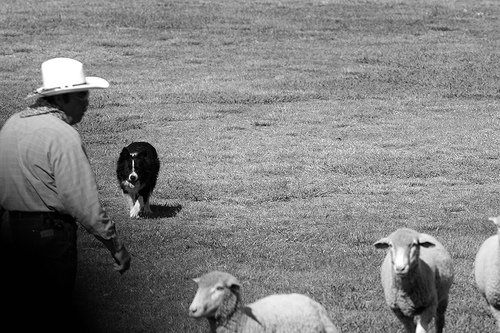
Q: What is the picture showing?
A: It is showing a field.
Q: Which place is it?
A: It is a field.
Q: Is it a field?
A: Yes, it is a field.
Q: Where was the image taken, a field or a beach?
A: It was taken at a field.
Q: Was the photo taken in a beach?
A: No, the picture was taken in a field.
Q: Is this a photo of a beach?
A: No, the picture is showing a field.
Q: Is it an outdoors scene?
A: Yes, it is outdoors.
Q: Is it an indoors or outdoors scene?
A: It is outdoors.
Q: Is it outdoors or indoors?
A: It is outdoors.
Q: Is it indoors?
A: No, it is outdoors.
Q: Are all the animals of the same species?
A: No, there are both sheep and dogs.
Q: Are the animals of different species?
A: Yes, they are sheep and dogs.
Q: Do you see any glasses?
A: No, there are no glasses.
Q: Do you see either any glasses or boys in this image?
A: No, there are no glasses or boys.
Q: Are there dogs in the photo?
A: Yes, there is a dog.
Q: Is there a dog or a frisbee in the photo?
A: Yes, there is a dog.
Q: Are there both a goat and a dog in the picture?
A: No, there is a dog but no goats.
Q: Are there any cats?
A: No, there are no cats.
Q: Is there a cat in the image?
A: No, there are no cats.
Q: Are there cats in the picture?
A: No, there are no cats.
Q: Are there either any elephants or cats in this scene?
A: No, there are no cats or elephants.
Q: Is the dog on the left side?
A: Yes, the dog is on the left of the image.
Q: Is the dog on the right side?
A: No, the dog is on the left of the image.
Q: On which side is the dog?
A: The dog is on the left of the image.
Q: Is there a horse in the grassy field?
A: No, there is a dog in the field.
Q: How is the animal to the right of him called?
A: The animal is a dog.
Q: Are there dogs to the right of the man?
A: Yes, there is a dog to the right of the man.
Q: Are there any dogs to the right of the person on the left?
A: Yes, there is a dog to the right of the man.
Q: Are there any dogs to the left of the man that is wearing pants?
A: No, the dog is to the right of the man.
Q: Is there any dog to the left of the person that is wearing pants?
A: No, the dog is to the right of the man.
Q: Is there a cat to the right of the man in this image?
A: No, there is a dog to the right of the man.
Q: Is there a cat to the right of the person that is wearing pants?
A: No, there is a dog to the right of the man.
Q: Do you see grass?
A: Yes, there is grass.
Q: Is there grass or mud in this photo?
A: Yes, there is grass.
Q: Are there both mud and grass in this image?
A: No, there is grass but no mud.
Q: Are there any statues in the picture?
A: No, there are no statues.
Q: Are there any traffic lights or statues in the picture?
A: No, there are no statues or traffic lights.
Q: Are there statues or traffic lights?
A: No, there are no statues or traffic lights.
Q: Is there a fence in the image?
A: No, there are no fences.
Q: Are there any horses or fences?
A: No, there are no fences or horses.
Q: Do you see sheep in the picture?
A: Yes, there is a sheep.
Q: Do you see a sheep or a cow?
A: Yes, there is a sheep.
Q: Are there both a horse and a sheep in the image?
A: No, there is a sheep but no horses.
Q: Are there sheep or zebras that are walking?
A: Yes, the sheep is walking.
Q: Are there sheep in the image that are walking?
A: Yes, there is a sheep that is walking.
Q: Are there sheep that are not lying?
A: Yes, there is a sheep that is walking.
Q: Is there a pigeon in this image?
A: No, there are no pigeons.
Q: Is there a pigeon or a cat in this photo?
A: No, there are no pigeons or cats.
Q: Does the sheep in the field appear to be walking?
A: Yes, the sheep is walking.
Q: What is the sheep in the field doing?
A: The sheep is walking.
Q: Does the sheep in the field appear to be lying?
A: No, the sheep is walking.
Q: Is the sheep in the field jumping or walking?
A: The sheep is walking.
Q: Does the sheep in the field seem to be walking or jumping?
A: The sheep is walking.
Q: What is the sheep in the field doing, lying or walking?
A: The sheep is walking.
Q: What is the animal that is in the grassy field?
A: The animal is a sheep.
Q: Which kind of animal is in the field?
A: The animal is a sheep.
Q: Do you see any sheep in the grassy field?
A: Yes, there is a sheep in the field.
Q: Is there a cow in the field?
A: No, there is a sheep in the field.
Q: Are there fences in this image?
A: No, there are no fences.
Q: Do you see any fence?
A: No, there are no fences.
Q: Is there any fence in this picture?
A: No, there are no fences.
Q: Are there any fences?
A: No, there are no fences.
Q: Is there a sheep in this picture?
A: Yes, there is a sheep.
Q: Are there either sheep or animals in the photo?
A: Yes, there is a sheep.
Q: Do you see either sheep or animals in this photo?
A: Yes, there is a sheep.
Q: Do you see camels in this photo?
A: No, there are no camels.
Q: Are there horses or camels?
A: No, there are no camels or horses.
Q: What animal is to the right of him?
A: The animal is a sheep.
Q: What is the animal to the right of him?
A: The animal is a sheep.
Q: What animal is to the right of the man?
A: The animal is a sheep.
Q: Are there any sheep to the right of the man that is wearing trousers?
A: Yes, there is a sheep to the right of the man.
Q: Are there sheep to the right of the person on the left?
A: Yes, there is a sheep to the right of the man.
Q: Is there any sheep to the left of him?
A: No, the sheep is to the right of the man.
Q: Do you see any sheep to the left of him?
A: No, the sheep is to the right of the man.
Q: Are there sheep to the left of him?
A: No, the sheep is to the right of the man.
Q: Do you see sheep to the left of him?
A: No, the sheep is to the right of the man.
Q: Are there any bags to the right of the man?
A: No, there is a sheep to the right of the man.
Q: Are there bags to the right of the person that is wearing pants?
A: No, there is a sheep to the right of the man.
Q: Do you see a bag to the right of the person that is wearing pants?
A: No, there is a sheep to the right of the man.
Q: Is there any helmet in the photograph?
A: No, there are no helmets.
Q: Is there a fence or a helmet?
A: No, there are no helmets or fences.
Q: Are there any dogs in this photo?
A: Yes, there is a dog.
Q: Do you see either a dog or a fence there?
A: Yes, there is a dog.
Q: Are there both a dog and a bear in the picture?
A: No, there is a dog but no bears.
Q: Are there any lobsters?
A: No, there are no lobsters.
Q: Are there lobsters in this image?
A: No, there are no lobsters.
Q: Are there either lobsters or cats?
A: No, there are no lobsters or cats.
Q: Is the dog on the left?
A: Yes, the dog is on the left of the image.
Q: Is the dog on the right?
A: No, the dog is on the left of the image.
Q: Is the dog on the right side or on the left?
A: The dog is on the left of the image.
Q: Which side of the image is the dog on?
A: The dog is on the left of the image.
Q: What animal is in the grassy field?
A: The animal is a dog.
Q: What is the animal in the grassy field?
A: The animal is a dog.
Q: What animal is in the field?
A: The animal is a dog.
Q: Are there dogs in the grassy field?
A: Yes, there is a dog in the field.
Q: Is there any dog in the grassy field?
A: Yes, there is a dog in the field.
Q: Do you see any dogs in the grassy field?
A: Yes, there is a dog in the field.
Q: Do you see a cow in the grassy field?
A: No, there is a dog in the field.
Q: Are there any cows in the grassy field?
A: No, there is a dog in the field.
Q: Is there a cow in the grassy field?
A: No, there is a dog in the field.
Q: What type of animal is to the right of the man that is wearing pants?
A: The animal is a dog.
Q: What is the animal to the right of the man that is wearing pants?
A: The animal is a dog.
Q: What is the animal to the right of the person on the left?
A: The animal is a dog.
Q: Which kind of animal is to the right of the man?
A: The animal is a dog.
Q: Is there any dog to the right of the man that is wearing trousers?
A: Yes, there is a dog to the right of the man.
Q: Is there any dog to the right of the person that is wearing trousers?
A: Yes, there is a dog to the right of the man.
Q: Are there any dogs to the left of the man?
A: No, the dog is to the right of the man.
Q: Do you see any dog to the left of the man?
A: No, the dog is to the right of the man.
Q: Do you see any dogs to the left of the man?
A: No, the dog is to the right of the man.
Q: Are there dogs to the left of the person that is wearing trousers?
A: No, the dog is to the right of the man.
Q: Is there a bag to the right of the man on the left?
A: No, there is a dog to the right of the man.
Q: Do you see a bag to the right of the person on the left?
A: No, there is a dog to the right of the man.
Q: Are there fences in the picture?
A: No, there are no fences.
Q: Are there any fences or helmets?
A: No, there are no fences or helmets.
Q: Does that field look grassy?
A: Yes, the field is grassy.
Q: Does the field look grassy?
A: Yes, the field is grassy.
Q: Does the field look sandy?
A: No, the field is grassy.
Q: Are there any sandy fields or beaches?
A: No, there is a field but it is grassy.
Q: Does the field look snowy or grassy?
A: The field is grassy.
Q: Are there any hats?
A: Yes, there is a hat.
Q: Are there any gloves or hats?
A: Yes, there is a hat.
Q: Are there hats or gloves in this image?
A: Yes, there is a hat.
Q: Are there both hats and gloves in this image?
A: Yes, there are both a hat and gloves.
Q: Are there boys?
A: No, there are no boys.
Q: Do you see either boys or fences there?
A: No, there are no boys or fences.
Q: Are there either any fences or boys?
A: No, there are no boys or fences.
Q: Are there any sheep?
A: Yes, there is a sheep.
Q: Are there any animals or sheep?
A: Yes, there is a sheep.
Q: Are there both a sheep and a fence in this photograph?
A: No, there is a sheep but no fences.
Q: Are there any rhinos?
A: No, there are no rhinos.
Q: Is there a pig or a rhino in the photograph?
A: No, there are no rhinos or pigs.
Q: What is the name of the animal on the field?
A: The animal is a sheep.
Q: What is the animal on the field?
A: The animal is a sheep.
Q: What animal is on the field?
A: The animal is a sheep.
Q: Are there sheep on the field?
A: Yes, there is a sheep on the field.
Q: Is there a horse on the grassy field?
A: No, there is a sheep on the field.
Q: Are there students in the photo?
A: No, there are no students.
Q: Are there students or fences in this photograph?
A: No, there are no students or fences.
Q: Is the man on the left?
A: Yes, the man is on the left of the image.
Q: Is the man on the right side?
A: No, the man is on the left of the image.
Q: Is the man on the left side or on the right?
A: The man is on the left of the image.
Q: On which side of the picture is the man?
A: The man is on the left of the image.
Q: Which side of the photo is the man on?
A: The man is on the left of the image.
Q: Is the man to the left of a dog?
A: Yes, the man is to the left of a dog.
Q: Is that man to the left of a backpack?
A: No, the man is to the left of a dog.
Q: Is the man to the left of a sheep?
A: Yes, the man is to the left of a sheep.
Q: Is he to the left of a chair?
A: No, the man is to the left of a sheep.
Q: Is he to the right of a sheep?
A: No, the man is to the left of a sheep.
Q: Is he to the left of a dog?
A: Yes, the man is to the left of a dog.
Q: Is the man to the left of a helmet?
A: No, the man is to the left of a dog.